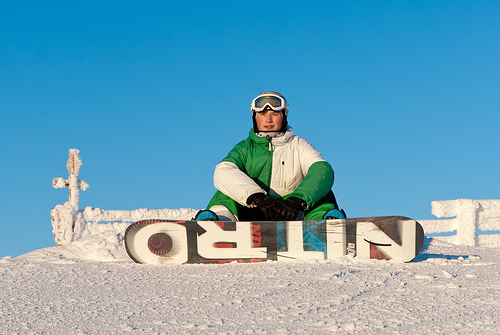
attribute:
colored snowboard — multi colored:
[124, 215, 423, 260]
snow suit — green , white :
[171, 120, 351, 219]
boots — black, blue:
[322, 210, 345, 219]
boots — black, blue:
[192, 207, 222, 219]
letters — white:
[131, 222, 414, 260]